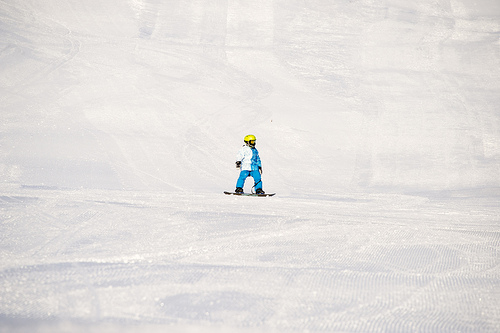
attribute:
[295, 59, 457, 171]
snow — white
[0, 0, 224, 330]
snow — white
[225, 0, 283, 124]
snow — white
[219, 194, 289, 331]
snow — white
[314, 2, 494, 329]
snow — white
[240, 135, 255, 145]
helmet — yellow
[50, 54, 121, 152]
snow — white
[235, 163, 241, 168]
gloves — black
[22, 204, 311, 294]
snow — white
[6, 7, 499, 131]
snow — white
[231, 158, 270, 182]
pants — blue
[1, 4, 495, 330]
snow — white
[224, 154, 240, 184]
glove — black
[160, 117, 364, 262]
snow — white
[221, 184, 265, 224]
boots — black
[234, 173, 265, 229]
pants — blue